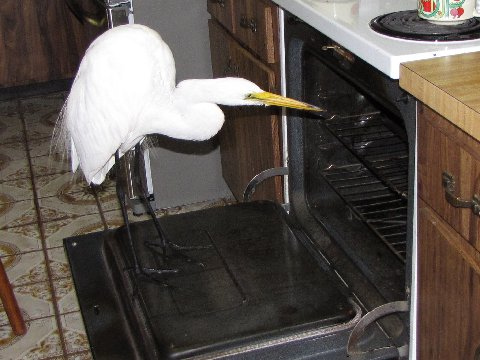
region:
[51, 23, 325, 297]
big white bird standing on open oven door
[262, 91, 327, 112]
beak of the big white bird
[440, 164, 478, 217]
drawer handle to the right of the bird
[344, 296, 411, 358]
foreground hinge of oven door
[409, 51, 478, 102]
top of countertop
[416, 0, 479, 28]
container sitting on a burner on stove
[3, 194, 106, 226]
floor behind the bird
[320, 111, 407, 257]
racks in the open oven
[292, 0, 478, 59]
top of the stove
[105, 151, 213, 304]
legs and feet of the white bird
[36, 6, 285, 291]
Flamingo is in the house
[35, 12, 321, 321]
The bird has black legs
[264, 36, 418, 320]
The inside of this stove is black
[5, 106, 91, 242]
A pattern on the floor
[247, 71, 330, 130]
Yellow is the color of the beak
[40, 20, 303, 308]
Bird is standing on the oven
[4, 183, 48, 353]
A stool in the corner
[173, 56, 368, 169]
The bird is looking in the oven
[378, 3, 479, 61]
Food is cooking on the stove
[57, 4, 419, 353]
The stove is open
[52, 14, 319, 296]
white crane is standing on oven door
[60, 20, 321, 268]
white crane has orange beak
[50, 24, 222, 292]
white crane has black legs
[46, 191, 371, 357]
oven door is open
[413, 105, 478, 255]
brown wooden drawer has brown handle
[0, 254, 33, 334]
brown chair leg is on patterned floor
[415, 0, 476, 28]
white mug with various colors is on stove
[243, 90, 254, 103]
white crane has right eye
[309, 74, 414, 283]
black oven has two racks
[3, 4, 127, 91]
brown paneling is on wall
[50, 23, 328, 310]
Crane looking in oven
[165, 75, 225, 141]
neck is curved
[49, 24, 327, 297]
crane is white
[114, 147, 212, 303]
crane with two black legs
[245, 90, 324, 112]
beak is yellow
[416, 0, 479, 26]
ceramic dish on oven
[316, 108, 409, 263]
two metal racks in oven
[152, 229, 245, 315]
oven door has burnt glass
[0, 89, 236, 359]
old brown tiles on floor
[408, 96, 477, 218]
kitchen draw with handle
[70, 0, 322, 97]
two kitchen draws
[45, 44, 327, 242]
a white pelicon with a yellow beak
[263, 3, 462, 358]
a oven with the oven door open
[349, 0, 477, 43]
a cup on a round on the stove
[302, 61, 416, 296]
two racks in the oven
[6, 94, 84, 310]
nanolum covering the kitchen floor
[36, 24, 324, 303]
a pelicon with black legs and feet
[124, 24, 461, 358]
a black oven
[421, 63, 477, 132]
a brown countertop